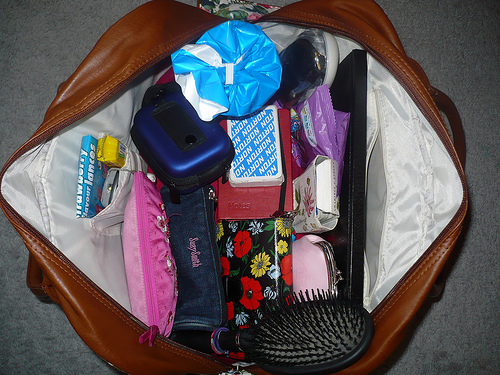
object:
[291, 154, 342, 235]
cigarrette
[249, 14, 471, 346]
zipper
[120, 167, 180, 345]
pouch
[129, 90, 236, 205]
case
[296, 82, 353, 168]
product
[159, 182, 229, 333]
case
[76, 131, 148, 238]
interior pocket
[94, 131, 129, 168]
candy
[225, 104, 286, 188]
cards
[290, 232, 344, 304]
pink pocketbook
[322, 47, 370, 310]
tablet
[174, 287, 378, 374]
hair brush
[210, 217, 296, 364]
case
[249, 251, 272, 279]
flower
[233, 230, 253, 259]
flower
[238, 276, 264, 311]
flower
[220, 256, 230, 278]
flower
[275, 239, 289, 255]
flower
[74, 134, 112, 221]
gum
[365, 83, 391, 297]
lining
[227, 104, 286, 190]
stack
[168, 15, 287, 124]
item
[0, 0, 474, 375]
bag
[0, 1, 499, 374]
background